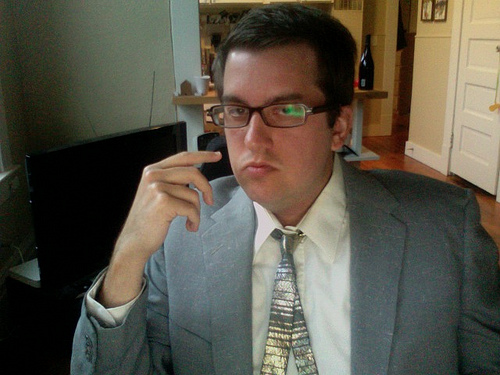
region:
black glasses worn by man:
[201, 93, 318, 137]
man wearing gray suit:
[121, 179, 451, 361]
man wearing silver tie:
[258, 234, 323, 374]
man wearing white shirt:
[236, 191, 361, 365]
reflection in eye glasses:
[269, 101, 307, 128]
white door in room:
[452, 11, 499, 183]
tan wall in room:
[18, 14, 153, 114]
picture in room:
[417, 4, 448, 26]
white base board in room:
[393, 135, 454, 173]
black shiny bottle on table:
[357, 33, 381, 100]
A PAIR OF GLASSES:
[206, 92, 363, 132]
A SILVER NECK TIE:
[252, 228, 337, 371]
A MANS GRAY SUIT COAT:
[65, 158, 494, 373]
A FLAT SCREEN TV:
[11, 111, 200, 313]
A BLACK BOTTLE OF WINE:
[353, 26, 395, 98]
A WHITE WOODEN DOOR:
[442, 5, 498, 204]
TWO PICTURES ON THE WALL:
[411, 0, 458, 32]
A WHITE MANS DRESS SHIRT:
[232, 147, 364, 372]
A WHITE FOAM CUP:
[191, 66, 213, 103]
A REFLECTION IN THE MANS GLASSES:
[204, 90, 321, 138]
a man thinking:
[76, 12, 498, 367]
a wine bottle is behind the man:
[195, 11, 412, 198]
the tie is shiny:
[233, 216, 345, 373]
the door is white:
[430, 0, 498, 205]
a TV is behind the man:
[12, 68, 228, 342]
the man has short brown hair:
[176, 5, 397, 230]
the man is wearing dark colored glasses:
[186, 7, 401, 241]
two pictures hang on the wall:
[398, 0, 462, 70]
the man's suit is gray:
[66, 139, 496, 371]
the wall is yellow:
[401, 17, 465, 170]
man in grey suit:
[68, 3, 498, 373]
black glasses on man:
[206, 94, 350, 131]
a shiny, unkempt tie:
[261, 226, 316, 373]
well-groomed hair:
[211, 2, 355, 124]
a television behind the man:
[19, 120, 187, 317]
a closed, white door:
[449, 0, 499, 199]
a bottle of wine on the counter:
[359, 31, 376, 89]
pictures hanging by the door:
[421, 0, 447, 21]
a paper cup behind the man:
[194, 73, 211, 95]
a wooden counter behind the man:
[171, 82, 386, 102]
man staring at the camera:
[74, 6, 498, 371]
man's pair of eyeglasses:
[205, 97, 339, 132]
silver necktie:
[259, 228, 326, 373]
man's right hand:
[95, 140, 224, 311]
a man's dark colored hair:
[206, 3, 359, 133]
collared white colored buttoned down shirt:
[237, 144, 361, 374]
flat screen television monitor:
[20, 116, 198, 298]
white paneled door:
[451, 0, 497, 193]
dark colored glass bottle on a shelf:
[358, 29, 378, 97]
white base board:
[403, 139, 450, 179]